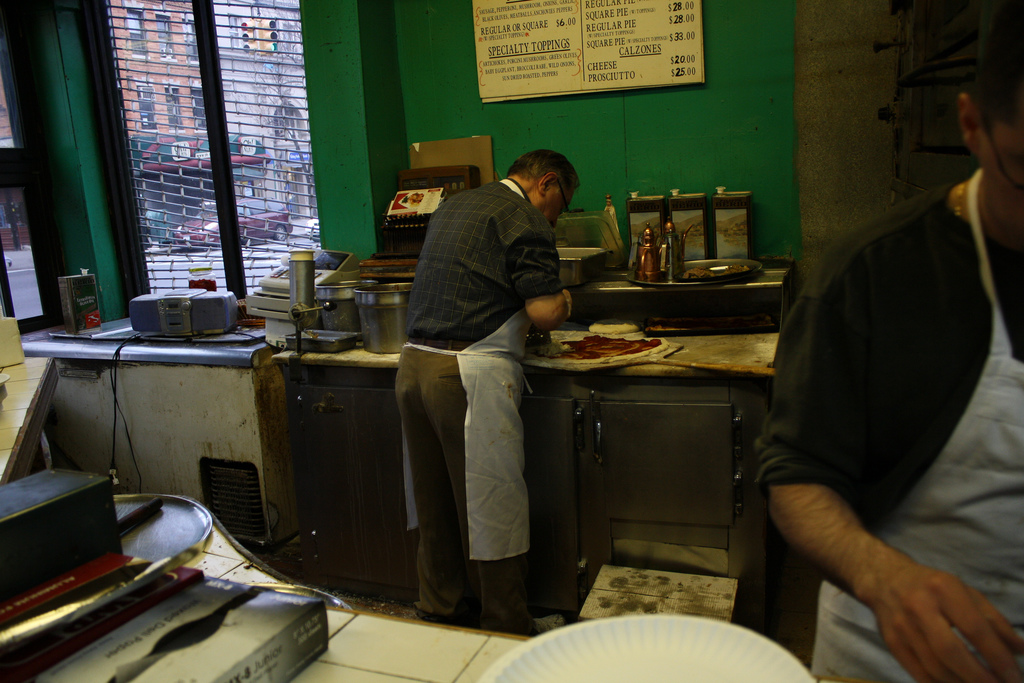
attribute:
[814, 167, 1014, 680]
apron — white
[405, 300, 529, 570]
apron — white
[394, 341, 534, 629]
pants — brown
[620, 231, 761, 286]
tray — round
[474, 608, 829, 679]
paper plate — white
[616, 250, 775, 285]
serving platter — silver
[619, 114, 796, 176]
wall — green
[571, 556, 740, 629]
white tiles — dirty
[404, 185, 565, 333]
shirt — black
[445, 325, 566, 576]
apron — white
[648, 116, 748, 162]
wall — green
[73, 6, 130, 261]
framed — aluminum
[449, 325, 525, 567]
apron — white